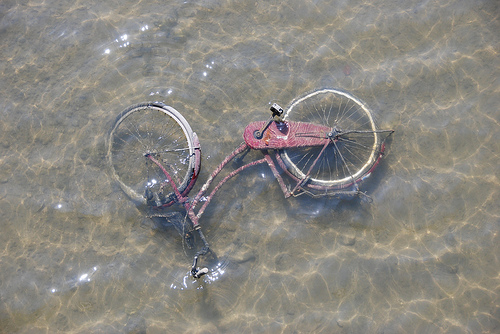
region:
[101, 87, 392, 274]
a bike in water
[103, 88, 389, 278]
a red bike submerged in water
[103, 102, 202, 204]
the wheel of the bicycle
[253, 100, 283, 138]
the pedal of the bike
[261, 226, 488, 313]
small waves in the water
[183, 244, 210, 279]
the handle bar of the bike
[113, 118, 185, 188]
spokes in the wheel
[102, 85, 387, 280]
an old bike laying down in water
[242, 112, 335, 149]
the chain box on the bike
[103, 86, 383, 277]
a bicycle that has been put in water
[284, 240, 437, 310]
ripples of water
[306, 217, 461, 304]
clear water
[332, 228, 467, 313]
sandy bottom of water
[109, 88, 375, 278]
bicycle laying in water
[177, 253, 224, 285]
handle bars for handling bike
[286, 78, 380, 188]
wheel helps bike move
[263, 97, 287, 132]
pedal for moving wheels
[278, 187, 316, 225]
missing seat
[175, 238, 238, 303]
handle bar sticking out of water, meaning water is shallow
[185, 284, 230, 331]
bike shadow under the water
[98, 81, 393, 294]
a bike color read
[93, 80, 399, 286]
an old bike in the water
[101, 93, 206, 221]
front wheel of bike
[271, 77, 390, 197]
back wheel of bike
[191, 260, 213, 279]
white handle of bike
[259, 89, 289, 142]
a pedal of bike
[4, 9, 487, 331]
light is reflected on the water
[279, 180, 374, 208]
sit of the bike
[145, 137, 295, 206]
frame of bike is red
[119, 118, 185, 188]
spokes of bike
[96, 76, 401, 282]
a bike inside a body of water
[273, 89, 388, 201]
back wheel of a bike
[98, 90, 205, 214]
front wheel of a bike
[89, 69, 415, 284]
an old abandoned bike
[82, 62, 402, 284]
a bike drenched in water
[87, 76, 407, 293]
a red bike in water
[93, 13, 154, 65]
reflections from the water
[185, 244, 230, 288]
handles of a bike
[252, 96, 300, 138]
pedals of a bike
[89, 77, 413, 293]
an old rusty bike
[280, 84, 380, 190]
The rear wheel of a bicycle.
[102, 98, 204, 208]
The front wheel of a bicycle.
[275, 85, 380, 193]
A fully submerged bicycle wheel.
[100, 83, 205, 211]
A partially submerged bicycle wheel.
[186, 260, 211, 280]
A partially submerged bicycle handle.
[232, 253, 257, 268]
A fully submerged bicycle handle.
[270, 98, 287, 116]
A bicycle pedal.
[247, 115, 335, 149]
A safety cover over a chain.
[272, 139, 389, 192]
The rear fender of the bicycle.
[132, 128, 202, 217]
The front fender of the bicycle.